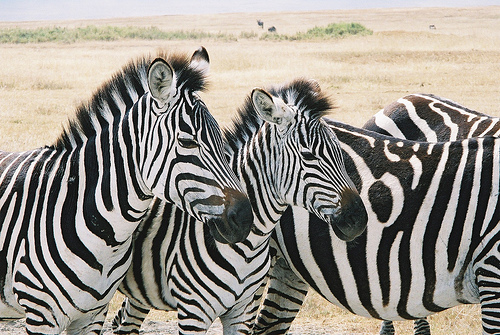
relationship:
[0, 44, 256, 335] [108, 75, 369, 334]
animal beside animal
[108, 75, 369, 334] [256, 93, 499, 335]
animal beside zebra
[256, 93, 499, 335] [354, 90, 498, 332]
zebra beside zebra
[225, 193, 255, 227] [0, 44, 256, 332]
nose on animal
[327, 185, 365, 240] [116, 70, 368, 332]
snout on animal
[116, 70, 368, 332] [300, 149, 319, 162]
animal has eye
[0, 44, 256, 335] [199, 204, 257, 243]
animal has nose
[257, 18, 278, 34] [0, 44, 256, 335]
animals behind animal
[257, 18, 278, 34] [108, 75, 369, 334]
animals behind animal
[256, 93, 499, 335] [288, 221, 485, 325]
zebra has belly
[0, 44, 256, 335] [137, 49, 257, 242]
animal has face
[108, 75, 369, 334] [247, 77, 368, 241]
animal has face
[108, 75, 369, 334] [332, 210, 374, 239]
animal has mouth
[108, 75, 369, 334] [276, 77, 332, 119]
animal has skin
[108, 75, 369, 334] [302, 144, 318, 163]
animal has eye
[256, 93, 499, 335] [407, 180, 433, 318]
zebra has skin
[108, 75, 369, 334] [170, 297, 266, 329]
animal has legs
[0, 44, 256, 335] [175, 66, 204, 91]
animal has mane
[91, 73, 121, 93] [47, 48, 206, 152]
hair on mane